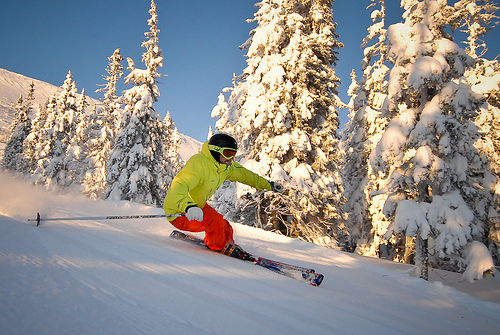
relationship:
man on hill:
[153, 142, 285, 263] [1, 69, 499, 334]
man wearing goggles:
[153, 142, 285, 263] [212, 143, 241, 162]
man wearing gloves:
[153, 142, 285, 263] [181, 175, 291, 225]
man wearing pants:
[153, 142, 285, 263] [166, 203, 248, 257]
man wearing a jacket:
[153, 142, 285, 263] [162, 147, 277, 216]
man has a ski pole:
[153, 142, 285, 263] [25, 202, 189, 230]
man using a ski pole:
[153, 142, 285, 263] [25, 202, 189, 230]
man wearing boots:
[153, 142, 285, 263] [214, 232, 254, 264]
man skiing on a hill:
[153, 142, 285, 263] [1, 69, 499, 334]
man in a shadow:
[153, 142, 285, 263] [0, 217, 495, 334]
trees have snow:
[2, 0, 500, 275] [10, 4, 500, 223]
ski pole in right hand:
[25, 202, 189, 230] [177, 205, 206, 224]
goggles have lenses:
[212, 143, 241, 162] [222, 149, 247, 159]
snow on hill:
[2, 68, 499, 335] [1, 69, 499, 334]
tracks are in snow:
[29, 196, 289, 333] [2, 68, 499, 335]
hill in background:
[1, 69, 499, 334] [2, 65, 498, 275]